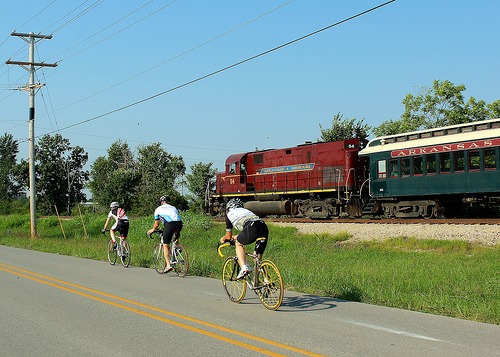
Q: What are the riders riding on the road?
A: Riders are riding bikes down the road.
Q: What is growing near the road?
A: There is a patch of grass growing near the road.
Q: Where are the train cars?
A: Train cars are on the train track.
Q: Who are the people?
A: Three bicyclists.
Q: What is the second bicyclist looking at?
A: At the train.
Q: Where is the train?
A: On the rail track.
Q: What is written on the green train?
A: "ARKANSAS".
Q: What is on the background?
A: Green trees.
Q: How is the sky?
A: Clear and blue.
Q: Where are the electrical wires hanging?
A: On a tall pole.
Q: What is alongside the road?
A: Green grass.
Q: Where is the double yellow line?
A: On the road.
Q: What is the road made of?
A: Asphalt.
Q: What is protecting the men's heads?
A: Helmet.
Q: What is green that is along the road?
A: Grass.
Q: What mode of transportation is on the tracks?
A: Train.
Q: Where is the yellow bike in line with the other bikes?
A: In the rear.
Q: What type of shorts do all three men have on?
A: Black bike shorts.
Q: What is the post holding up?
A: Electrical lines.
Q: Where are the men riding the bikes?
A: Street shoulder.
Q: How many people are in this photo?
A: Three.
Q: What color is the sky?
A: Blue.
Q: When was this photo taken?
A: Outside, during the daytime.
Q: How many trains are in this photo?
A: One.